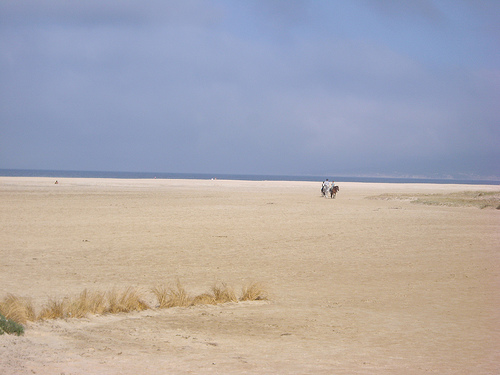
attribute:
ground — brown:
[1, 178, 495, 374]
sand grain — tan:
[260, 228, 265, 230]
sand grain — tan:
[222, 222, 228, 224]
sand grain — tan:
[217, 230, 223, 233]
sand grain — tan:
[172, 217, 176, 219]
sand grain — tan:
[172, 227, 175, 229]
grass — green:
[36, 282, 231, 342]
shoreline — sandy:
[1, 176, 498, 191]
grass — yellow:
[58, 265, 295, 327]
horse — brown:
[327, 186, 339, 201]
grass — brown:
[2, 279, 268, 336]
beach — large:
[2, 176, 499, 374]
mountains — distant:
[298, 170, 498, 180]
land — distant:
[304, 170, 499, 182]